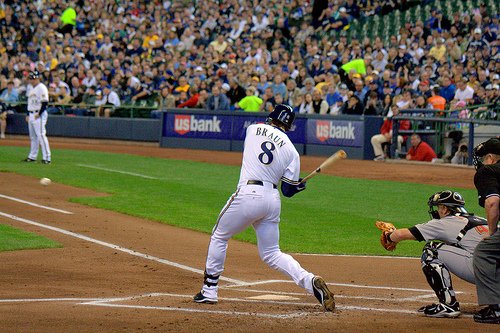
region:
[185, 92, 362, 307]
a baseball player swinging his bat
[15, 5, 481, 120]
the crowd watching the baseball game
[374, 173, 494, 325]
a catcher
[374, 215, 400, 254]
a baseball glove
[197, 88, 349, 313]
a man playing baseball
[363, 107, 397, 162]
a person watching the game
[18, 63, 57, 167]
a player that catches the ball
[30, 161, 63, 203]
a baseball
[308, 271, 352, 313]
a shoe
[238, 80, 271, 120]
a person in the crowd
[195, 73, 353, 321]
A baseball player swinging a bat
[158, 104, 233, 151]
An ad for US Bank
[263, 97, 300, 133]
A batter's helmet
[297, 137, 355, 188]
A wooden baseball bat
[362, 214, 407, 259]
A catcher's mitt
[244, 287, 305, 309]
Home plate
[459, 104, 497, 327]
Partial view of an umpire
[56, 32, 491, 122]
Spectators watching a baseball game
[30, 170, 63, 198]
A baseball flying through the air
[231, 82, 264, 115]
A person in a neon green shirt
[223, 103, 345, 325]
White and blue baseball uniform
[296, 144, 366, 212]
Bat in a baseball player's hand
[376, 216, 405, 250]
Glove on a baseball player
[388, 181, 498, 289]
Baseball player in a gray uniform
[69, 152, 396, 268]
Grass and dirt on a baseball field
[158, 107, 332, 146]
Us bank sign on a field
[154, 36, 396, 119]
Crowd watching a baseball game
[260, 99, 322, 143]
Blue helmet on a baseball player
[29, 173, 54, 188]
Baseball flying through the air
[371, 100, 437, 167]
Man in a red jacket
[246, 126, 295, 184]
This player is number 8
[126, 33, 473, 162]
Fans are in the stands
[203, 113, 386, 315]
The player is hitting the ball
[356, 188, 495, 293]
The catcher has a mitt on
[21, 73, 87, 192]
There is a player to the side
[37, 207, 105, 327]
Lines are on the ground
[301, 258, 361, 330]
The player has cleats on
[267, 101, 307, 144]
The player has a blue helmet on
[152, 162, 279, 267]
The grass is green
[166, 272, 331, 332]
The player is standing in the dirt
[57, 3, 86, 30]
a vendor wears a bright green shirt in the stands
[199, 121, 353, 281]
Player number 8 is at the bat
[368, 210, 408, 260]
the catchers mitt.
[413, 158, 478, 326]
the catcher waits for the ball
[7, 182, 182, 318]
the chalk lines of the baseball diamond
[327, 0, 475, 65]
An empty area in the stands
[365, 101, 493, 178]
Men watching from the dugout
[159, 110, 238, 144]
game sponsor banner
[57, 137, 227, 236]
grassy are of the playing field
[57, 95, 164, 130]
Steel railing on the bleachers